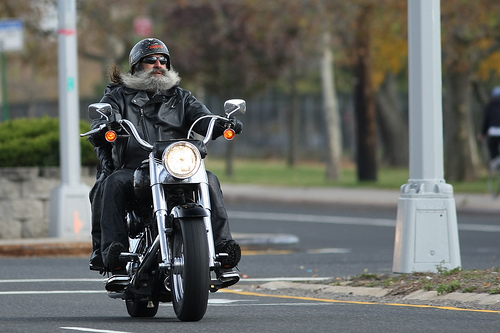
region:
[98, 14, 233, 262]
man riding a motor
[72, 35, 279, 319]
man riding a motor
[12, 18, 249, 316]
man riding on motor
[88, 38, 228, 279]
man riding on motor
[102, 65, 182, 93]
long grey beard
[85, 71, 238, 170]
shiny black leather jaclet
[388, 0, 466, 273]
grey metal lamp pole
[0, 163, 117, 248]
short grey brick wall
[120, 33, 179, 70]
black plastic helmet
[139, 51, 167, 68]
shiny black plastic sun glasses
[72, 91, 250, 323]
shiny black and silver motor cycle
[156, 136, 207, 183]
pale yellow illuminated head light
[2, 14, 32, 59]
white and blue street sign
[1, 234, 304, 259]
stone side walk curb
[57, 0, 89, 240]
Gray light post with red and green stickers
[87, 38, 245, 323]
man on a motorcycle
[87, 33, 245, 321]
biker with a long gray beard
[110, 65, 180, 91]
long gray beard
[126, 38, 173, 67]
black motorcycle helmet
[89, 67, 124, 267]
person sitting behind man with beard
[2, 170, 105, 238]
brick wall.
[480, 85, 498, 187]
person in dark outfit walking across the street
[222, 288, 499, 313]
Yellow line on the road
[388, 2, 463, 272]
gray light post on the right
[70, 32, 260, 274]
man riding a bike